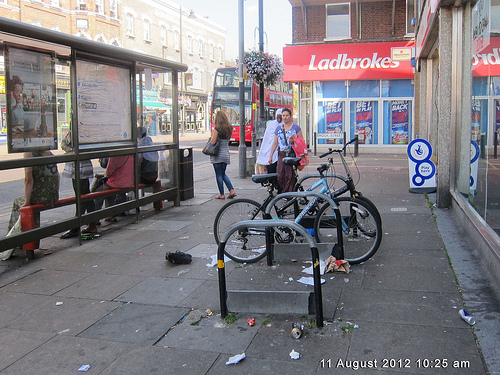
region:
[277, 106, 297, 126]
the head of a person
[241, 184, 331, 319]
a bicycle rack on the sidewalk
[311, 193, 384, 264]
the wheel of a bicycle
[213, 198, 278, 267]
the wheel of a bicycle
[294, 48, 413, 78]
a red sign with white letters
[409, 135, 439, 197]
a blue and white sign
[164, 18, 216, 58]
the windows of a building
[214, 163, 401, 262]
a bicycle on the sidewalk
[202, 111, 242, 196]
a woman holding a brown bag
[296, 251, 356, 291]
trash on the sidewalk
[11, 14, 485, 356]
a street scene at daytime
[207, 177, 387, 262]
bike locked to a bike rack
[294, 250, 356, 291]
trash on the ground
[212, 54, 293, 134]
red bus approaching the bus stop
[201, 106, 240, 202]
woman carrying a black bag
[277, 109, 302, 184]
woman wearing a purple shirt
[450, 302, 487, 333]
a can on the ground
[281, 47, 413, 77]
red and white sign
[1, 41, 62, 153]
advertisement on bus stop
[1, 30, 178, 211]
bus stop with glass panels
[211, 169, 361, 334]
gray and black bike rack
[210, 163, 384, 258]
bicycles parked at the bike rack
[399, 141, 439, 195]
outdoor display for the business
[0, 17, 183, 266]
bus stop next to the road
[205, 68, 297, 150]
red double decker bus on the road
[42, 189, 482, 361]
trash on the sidewalk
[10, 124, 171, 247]
people waiting at the bus stop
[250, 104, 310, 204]
people walking on the side walk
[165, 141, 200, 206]
black trash can next to the bus stop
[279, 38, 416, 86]
red sign that says Ladbrokes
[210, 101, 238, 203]
A woman walking to the road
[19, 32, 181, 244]
A bus stop waiting bay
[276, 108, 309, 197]
Woman carrying a sweater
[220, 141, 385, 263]
A biycle parked outside ta shop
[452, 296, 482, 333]
Empty energy drink bottle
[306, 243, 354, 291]
Litter on the ground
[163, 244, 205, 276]
A black polythene paper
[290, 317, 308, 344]
An empty beer bottle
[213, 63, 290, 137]
A big red bus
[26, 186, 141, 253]
A red stage seat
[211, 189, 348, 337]
black and silver bicycle rack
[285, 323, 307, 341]
aluminum can on concrete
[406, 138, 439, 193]
blue and white sign on building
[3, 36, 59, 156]
sign on bus stop waiting area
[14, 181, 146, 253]
red bench at bust stop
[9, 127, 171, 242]
people waiting on a bus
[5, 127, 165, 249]
people sitting on a bench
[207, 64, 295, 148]
red bus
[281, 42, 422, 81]
red awning on store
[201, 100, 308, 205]
people walking on sidewalk